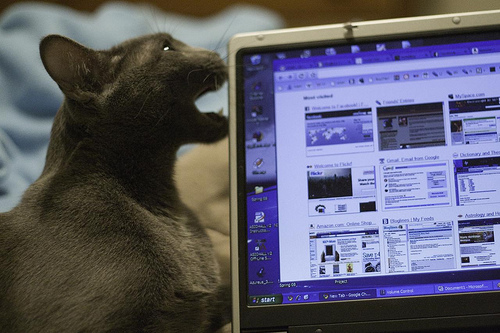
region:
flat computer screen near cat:
[217, 5, 497, 330]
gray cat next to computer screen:
[0, 25, 245, 330]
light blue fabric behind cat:
[0, 0, 295, 215]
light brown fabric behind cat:
[125, 61, 307, 327]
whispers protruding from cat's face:
[120, 5, 265, 142]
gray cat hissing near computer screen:
[0, 17, 245, 327]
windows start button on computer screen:
[245, 290, 290, 305]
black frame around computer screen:
[235, 25, 497, 331]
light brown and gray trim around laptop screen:
[224, 9, 498, 331]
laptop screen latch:
[338, 18, 371, 38]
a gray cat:
[0, 28, 232, 331]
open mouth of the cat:
[192, 75, 226, 132]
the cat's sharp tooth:
[216, 106, 225, 116]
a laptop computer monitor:
[227, 6, 499, 331]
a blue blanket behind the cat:
[0, 0, 287, 213]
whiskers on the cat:
[186, 11, 243, 96]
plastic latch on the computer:
[343, 20, 359, 30]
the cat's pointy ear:
[40, 32, 106, 102]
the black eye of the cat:
[160, 39, 175, 51]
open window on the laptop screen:
[273, 40, 499, 285]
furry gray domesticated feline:
[0, 11, 232, 332]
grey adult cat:
[0, 12, 237, 332]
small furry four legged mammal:
[5, 15, 233, 327]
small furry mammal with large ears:
[2, 11, 227, 326]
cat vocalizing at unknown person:
[1, 14, 238, 331]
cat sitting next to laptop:
[0, 11, 236, 332]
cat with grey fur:
[0, 7, 246, 332]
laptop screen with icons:
[209, 13, 497, 331]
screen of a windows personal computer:
[217, 17, 497, 332]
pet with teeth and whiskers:
[3, 10, 231, 332]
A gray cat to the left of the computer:
[5, 16, 235, 322]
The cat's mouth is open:
[141, 40, 228, 155]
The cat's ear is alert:
[30, 30, 125, 120]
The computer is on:
[225, 0, 495, 330]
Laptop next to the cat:
[225, 11, 495, 326]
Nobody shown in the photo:
[15, 0, 491, 325]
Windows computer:
[240, 5, 495, 316]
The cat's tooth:
[210, 101, 226, 118]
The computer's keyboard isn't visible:
[220, 15, 492, 325]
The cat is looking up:
[45, 10, 245, 151]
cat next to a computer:
[16, 10, 496, 310]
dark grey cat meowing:
[14, 16, 228, 328]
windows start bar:
[234, 291, 289, 309]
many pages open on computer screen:
[281, 96, 496, 283]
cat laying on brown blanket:
[4, 3, 229, 328]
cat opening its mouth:
[14, 17, 231, 289]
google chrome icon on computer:
[285, 291, 296, 305]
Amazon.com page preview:
[294, 220, 397, 279]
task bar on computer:
[236, 271, 498, 316]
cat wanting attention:
[0, 12, 237, 300]